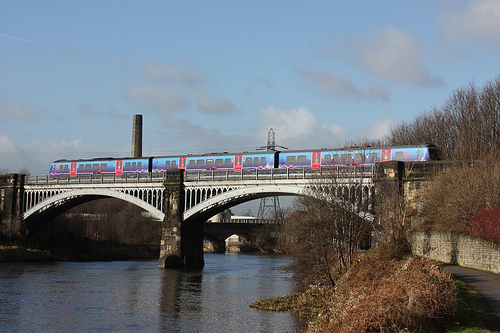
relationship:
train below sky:
[47, 141, 436, 174] [0, 1, 499, 139]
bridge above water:
[0, 166, 416, 255] [0, 248, 319, 332]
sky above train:
[0, 1, 499, 139] [47, 141, 436, 174]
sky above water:
[0, 1, 499, 139] [0, 248, 319, 332]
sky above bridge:
[0, 1, 499, 139] [0, 166, 416, 255]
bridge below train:
[0, 166, 416, 255] [47, 141, 436, 174]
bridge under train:
[0, 166, 416, 255] [47, 141, 436, 174]